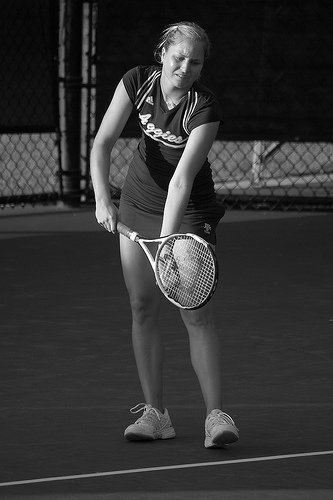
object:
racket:
[112, 216, 220, 312]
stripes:
[187, 88, 201, 121]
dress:
[110, 62, 228, 247]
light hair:
[151, 20, 209, 60]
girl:
[87, 20, 242, 452]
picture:
[0, 2, 333, 499]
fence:
[0, 1, 333, 213]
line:
[0, 441, 333, 486]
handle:
[93, 209, 140, 247]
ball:
[158, 271, 169, 292]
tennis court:
[0, 199, 333, 499]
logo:
[162, 246, 202, 291]